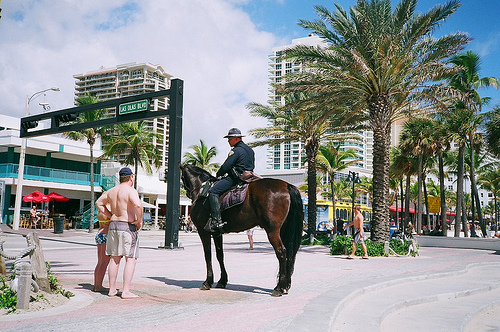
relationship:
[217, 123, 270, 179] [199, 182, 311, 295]
officer on horse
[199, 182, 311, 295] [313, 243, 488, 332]
horse in street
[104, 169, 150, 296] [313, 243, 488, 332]
man on street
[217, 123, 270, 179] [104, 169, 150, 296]
officer near man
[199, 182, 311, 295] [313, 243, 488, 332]
horse on street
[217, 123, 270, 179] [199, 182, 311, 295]
officer in horse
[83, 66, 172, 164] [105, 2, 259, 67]
building in sky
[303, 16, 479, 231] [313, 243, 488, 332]
tree on street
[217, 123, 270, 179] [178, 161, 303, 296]
officer on horse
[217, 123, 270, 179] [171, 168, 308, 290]
officer on horse